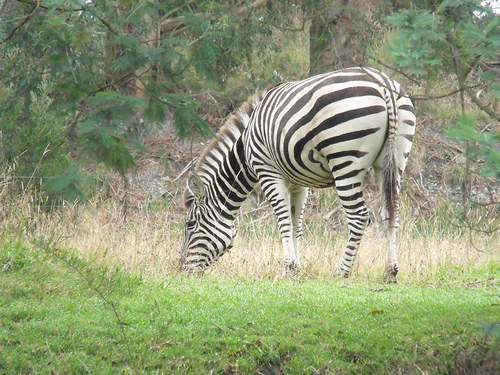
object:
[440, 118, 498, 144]
green leaves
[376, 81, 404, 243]
tail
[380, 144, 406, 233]
fur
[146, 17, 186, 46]
branches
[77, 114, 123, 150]
leaves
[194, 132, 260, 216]
neck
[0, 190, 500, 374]
ground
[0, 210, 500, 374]
grass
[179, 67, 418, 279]
zebra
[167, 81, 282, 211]
hair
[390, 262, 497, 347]
patch